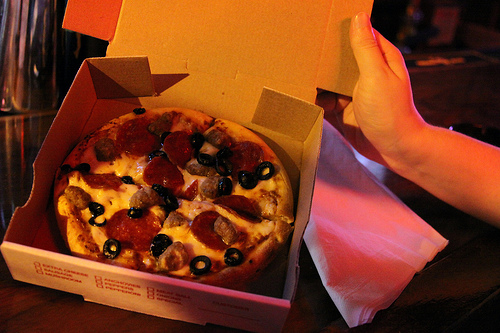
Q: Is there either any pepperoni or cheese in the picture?
A: Yes, there is pepperoni.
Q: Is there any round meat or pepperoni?
A: Yes, there is round pepperoni.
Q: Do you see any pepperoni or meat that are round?
A: Yes, the pepperoni is round.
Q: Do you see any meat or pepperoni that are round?
A: Yes, the pepperoni is round.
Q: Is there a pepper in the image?
A: No, there are no peppers.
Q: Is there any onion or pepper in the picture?
A: No, there are no peppers or onions.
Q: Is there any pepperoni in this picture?
A: Yes, there is pepperoni.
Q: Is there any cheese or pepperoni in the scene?
A: Yes, there is pepperoni.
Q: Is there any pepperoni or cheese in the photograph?
A: Yes, there is pepperoni.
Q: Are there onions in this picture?
A: No, there are no onions.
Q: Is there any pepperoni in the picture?
A: Yes, there is pepperoni.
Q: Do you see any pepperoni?
A: Yes, there is pepperoni.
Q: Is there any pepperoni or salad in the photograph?
A: Yes, there is pepperoni.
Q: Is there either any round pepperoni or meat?
A: Yes, there is round pepperoni.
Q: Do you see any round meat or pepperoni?
A: Yes, there is round pepperoni.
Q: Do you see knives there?
A: No, there are no knives.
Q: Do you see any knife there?
A: No, there are no knives.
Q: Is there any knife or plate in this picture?
A: No, there are no knives or plates.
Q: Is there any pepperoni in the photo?
A: Yes, there is pepperoni.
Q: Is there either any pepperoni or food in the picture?
A: Yes, there is pepperoni.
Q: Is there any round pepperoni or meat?
A: Yes, there is round pepperoni.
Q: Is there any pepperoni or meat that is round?
A: Yes, the pepperoni is round.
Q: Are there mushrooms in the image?
A: No, there are no mushrooms.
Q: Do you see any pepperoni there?
A: Yes, there is pepperoni.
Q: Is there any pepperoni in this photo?
A: Yes, there is pepperoni.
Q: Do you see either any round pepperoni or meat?
A: Yes, there is round pepperoni.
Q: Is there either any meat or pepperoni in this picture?
A: Yes, there is pepperoni.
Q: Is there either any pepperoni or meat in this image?
A: Yes, there is pepperoni.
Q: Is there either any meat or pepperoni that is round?
A: Yes, the pepperoni is round.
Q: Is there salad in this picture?
A: No, there is no salad.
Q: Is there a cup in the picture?
A: No, there are no cups.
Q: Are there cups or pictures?
A: No, there are no cups or pictures.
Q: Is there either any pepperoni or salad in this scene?
A: Yes, there is pepperoni.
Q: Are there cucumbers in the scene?
A: No, there are no cucumbers.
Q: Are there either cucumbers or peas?
A: No, there are no cucumbers or peas.